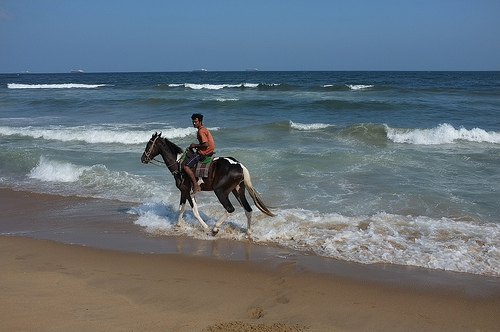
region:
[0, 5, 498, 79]
The sky is clear.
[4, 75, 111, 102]
The white foam from the waves.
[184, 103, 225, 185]
The man riding the horse.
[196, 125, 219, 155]
The man is wearing a red shirt.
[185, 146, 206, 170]
The man is wearing black pants.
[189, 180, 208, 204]
The man is not wearing shoes.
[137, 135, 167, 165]
The face of the horse.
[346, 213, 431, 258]
the water is white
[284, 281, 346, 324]
the sand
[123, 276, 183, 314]
the sand on the beach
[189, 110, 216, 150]
the man on the horse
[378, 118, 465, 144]
a wave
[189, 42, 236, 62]
a clear blue sky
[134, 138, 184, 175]
a black horse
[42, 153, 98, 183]
water is white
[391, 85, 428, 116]
the blue water in the ocean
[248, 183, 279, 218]
the horses tail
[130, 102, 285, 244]
man riding a horse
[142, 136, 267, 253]
a black and white horse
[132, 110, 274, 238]
Man riding on a horse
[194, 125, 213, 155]
Orange shirt on a man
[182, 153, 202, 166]
Black shorts on a man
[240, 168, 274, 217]
Long tail on a horse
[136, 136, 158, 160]
Bridle on a horse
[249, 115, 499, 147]
Wave in the ocean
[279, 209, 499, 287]
Water washing onto the shore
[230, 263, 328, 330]
Footprints in the sand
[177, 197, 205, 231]
White legs on a horse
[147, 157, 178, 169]
Reins on a horse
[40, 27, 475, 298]
the ocean is here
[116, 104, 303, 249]
the man is on a horse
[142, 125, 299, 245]
the horse is black and white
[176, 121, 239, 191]
the horse is saddled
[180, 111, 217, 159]
the man has dark skin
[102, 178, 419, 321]
the waves are small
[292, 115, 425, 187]
the ocean is green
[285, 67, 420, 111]
the ocean is blue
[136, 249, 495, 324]
the beach is sandy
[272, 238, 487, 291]
the sand is wet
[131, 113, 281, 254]
boy on horse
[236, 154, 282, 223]
horse with white tail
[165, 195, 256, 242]
horse has white feet